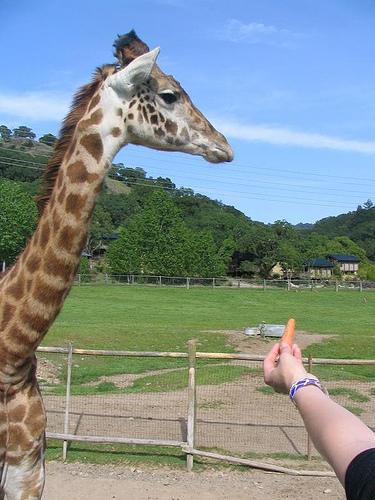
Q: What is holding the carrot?
A: A person's hand.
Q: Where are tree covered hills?
A: In background.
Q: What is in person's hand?
A: Carrot.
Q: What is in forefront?
A: Giraffe.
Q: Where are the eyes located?
A: Head of giraffe.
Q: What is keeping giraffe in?
A: The fence.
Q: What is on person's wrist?
A: Bracelet.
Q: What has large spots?
A: Giraffe.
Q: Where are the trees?
A: Background.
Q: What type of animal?
A: Giraffe.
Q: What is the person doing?
A: Trying to feed the giraffe.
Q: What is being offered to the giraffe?
A: Carrot.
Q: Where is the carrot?
A: In the person's hand.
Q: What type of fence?
A: Wood.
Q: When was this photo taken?
A: Daytime.